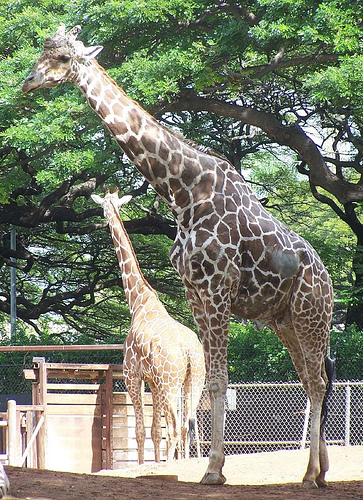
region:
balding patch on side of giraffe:
[246, 235, 316, 306]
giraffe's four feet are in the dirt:
[163, 446, 339, 497]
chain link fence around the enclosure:
[232, 326, 354, 490]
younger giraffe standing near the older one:
[75, 174, 315, 474]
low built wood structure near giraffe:
[13, 343, 203, 486]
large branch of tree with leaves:
[21, 263, 107, 354]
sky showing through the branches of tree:
[207, 88, 362, 198]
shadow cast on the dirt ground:
[256, 445, 319, 495]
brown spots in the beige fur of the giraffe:
[146, 142, 207, 201]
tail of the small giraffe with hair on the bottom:
[178, 352, 200, 445]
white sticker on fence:
[194, 389, 238, 411]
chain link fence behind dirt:
[0, 365, 361, 454]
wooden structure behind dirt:
[3, 355, 187, 476]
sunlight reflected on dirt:
[88, 438, 362, 484]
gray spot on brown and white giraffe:
[266, 242, 302, 278]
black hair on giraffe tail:
[316, 356, 339, 438]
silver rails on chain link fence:
[0, 360, 361, 458]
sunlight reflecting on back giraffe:
[85, 188, 209, 462]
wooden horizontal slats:
[45, 383, 178, 470]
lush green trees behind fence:
[0, 0, 362, 457]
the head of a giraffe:
[21, 26, 99, 104]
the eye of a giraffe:
[49, 20, 89, 74]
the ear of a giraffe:
[72, 30, 113, 73]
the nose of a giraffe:
[21, 58, 49, 104]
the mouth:
[21, 59, 45, 100]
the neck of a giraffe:
[72, 67, 227, 267]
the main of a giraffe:
[93, 72, 236, 226]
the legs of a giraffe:
[183, 266, 300, 469]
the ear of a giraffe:
[43, 34, 118, 68]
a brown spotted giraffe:
[68, 121, 236, 388]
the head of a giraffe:
[14, 1, 145, 88]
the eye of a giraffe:
[44, 46, 76, 83]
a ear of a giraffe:
[67, 34, 111, 75]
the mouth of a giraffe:
[17, 71, 60, 110]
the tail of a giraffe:
[302, 282, 359, 429]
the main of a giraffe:
[88, 205, 158, 321]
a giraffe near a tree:
[61, 46, 292, 257]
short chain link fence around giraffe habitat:
[234, 363, 300, 464]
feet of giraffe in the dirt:
[173, 448, 339, 495]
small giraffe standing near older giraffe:
[80, 179, 231, 484]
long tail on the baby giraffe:
[176, 343, 197, 447]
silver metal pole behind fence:
[4, 262, 23, 354]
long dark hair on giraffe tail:
[321, 348, 338, 450]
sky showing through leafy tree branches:
[226, 57, 361, 201]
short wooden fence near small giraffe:
[9, 339, 188, 465]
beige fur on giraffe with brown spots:
[195, 281, 228, 340]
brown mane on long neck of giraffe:
[106, 200, 169, 313]